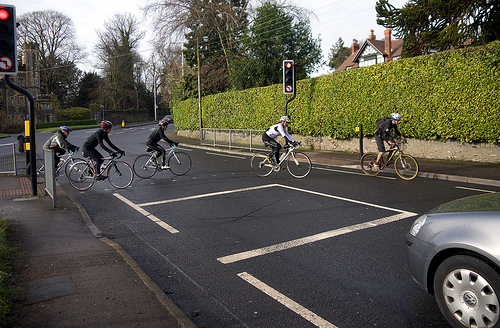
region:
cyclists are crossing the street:
[30, 101, 423, 203]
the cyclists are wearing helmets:
[37, 110, 413, 158]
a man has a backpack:
[370, 110, 405, 160]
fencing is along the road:
[41, 145, 61, 208]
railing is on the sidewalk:
[195, 116, 276, 166]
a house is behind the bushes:
[332, 27, 402, 184]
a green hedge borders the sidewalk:
[170, 43, 496, 174]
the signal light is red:
[1, 3, 41, 198]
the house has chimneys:
[333, 21, 474, 77]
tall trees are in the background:
[12, 1, 497, 139]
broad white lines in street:
[183, 227, 317, 287]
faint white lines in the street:
[179, 263, 204, 293]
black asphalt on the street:
[215, 209, 296, 226]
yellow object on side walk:
[19, 114, 36, 154]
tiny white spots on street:
[221, 292, 269, 317]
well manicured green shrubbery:
[335, 67, 494, 104]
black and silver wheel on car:
[443, 267, 499, 320]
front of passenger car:
[401, 184, 476, 244]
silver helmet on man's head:
[385, 107, 415, 127]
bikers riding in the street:
[60, 120, 438, 200]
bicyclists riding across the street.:
[40, 35, 443, 240]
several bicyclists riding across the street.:
[21, 100, 443, 200]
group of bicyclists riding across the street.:
[15, 56, 455, 181]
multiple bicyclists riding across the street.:
[20, 45, 445, 197]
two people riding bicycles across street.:
[210, 90, 435, 196]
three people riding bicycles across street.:
[120, 40, 440, 190]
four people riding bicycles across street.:
[70, 61, 442, 201]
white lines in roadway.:
[195, 220, 325, 317]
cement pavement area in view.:
[185, 200, 292, 232]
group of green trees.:
[41, 15, 276, 75]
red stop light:
[261, 47, 331, 123]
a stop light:
[256, 42, 334, 135]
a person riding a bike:
[243, 97, 323, 204]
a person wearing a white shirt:
[221, 89, 338, 229]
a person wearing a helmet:
[236, 102, 322, 190]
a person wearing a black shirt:
[350, 89, 412, 190]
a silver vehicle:
[391, 169, 499, 283]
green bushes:
[197, 56, 489, 171]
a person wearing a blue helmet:
[39, 114, 91, 199]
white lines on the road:
[107, 182, 424, 276]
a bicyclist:
[361, 114, 417, 175]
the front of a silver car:
[413, 191, 496, 306]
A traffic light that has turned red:
[1, 0, 29, 78]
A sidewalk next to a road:
[2, 174, 104, 325]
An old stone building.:
[0, 50, 59, 120]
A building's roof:
[335, 40, 469, 68]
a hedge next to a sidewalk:
[168, 91, 498, 126]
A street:
[75, 126, 478, 313]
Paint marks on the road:
[116, 193, 388, 320]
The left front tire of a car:
[438, 255, 496, 325]